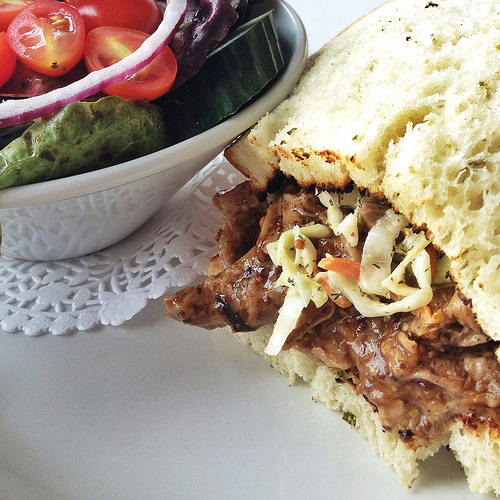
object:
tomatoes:
[81, 26, 179, 104]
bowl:
[2, 3, 310, 259]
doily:
[1, 157, 247, 341]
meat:
[163, 167, 499, 452]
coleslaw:
[254, 188, 438, 360]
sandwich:
[163, 3, 498, 498]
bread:
[219, 0, 500, 345]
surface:
[3, 1, 500, 500]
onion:
[2, 1, 192, 129]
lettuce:
[0, 93, 170, 193]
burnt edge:
[267, 142, 499, 367]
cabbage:
[170, 0, 239, 88]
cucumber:
[160, 9, 286, 140]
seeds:
[340, 409, 358, 428]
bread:
[215, 320, 498, 497]